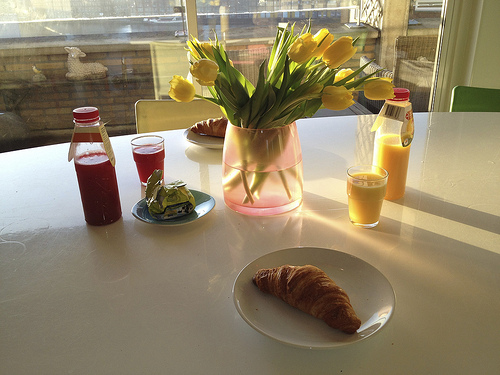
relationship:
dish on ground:
[232, 246, 397, 350] [0, 110, 500, 375]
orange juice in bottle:
[347, 137, 408, 224] [365, 78, 416, 210]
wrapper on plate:
[144, 169, 194, 217] [194, 190, 212, 216]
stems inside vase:
[242, 85, 294, 123] [209, 118, 316, 214]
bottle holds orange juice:
[370, 88, 415, 200] [366, 132, 408, 200]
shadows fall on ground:
[407, 180, 496, 291] [0, 110, 500, 375]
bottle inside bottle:
[68, 107, 123, 226] [69, 103, 123, 230]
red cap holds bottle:
[70, 104, 101, 123] [68, 107, 123, 226]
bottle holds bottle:
[69, 103, 123, 230] [68, 107, 123, 226]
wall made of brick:
[11, 60, 142, 104] [18, 73, 38, 101]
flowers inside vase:
[164, 21, 401, 124] [215, 122, 306, 221]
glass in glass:
[346, 165, 389, 229] [343, 156, 396, 237]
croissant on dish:
[246, 262, 364, 336] [232, 246, 397, 350]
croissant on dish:
[251, 265, 362, 335] [232, 246, 397, 350]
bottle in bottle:
[370, 88, 415, 200] [371, 95, 414, 198]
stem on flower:
[248, 52, 283, 121] [325, 30, 369, 72]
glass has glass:
[123, 129, 172, 183] [130, 135, 165, 186]